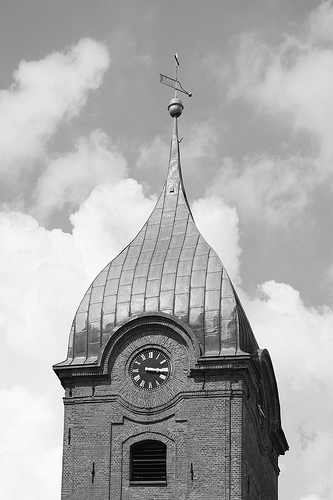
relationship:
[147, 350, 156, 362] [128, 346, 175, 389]
roman numerals on clock face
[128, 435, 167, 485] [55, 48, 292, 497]
vent on clock tower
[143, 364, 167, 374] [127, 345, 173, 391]
arms on clock face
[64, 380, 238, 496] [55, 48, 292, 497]
brick wall on clock tower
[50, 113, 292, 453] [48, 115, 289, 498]
roof on clock tower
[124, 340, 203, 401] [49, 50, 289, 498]
clock in tower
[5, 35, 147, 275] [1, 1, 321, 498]
clouds in sky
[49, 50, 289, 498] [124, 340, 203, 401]
tower has clock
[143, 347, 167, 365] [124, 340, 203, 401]
numbers on clock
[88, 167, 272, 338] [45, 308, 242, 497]
roofing on building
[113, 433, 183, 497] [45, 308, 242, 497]
windows on building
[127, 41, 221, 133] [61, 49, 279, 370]
ornament on steeple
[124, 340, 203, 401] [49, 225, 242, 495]
clock on building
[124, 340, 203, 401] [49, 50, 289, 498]
clock on top of tower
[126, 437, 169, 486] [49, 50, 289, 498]
window on top of tower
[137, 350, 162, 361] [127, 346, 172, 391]
numerals on a clock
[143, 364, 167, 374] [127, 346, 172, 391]
arms of a clock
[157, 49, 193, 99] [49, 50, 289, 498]
vane on top of tower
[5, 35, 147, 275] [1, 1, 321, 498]
clouds spread through sky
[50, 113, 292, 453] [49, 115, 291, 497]
roof of tower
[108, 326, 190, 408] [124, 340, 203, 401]
bricks around clock